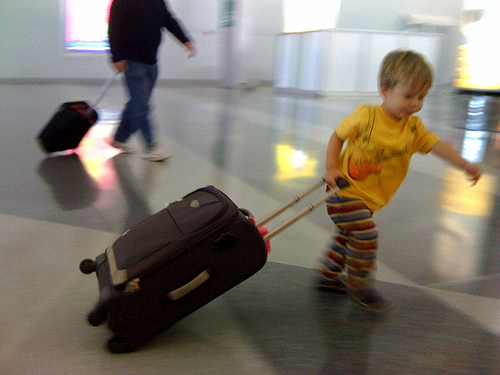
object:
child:
[309, 49, 484, 313]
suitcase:
[78, 174, 350, 355]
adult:
[102, 0, 198, 160]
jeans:
[115, 62, 160, 147]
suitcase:
[35, 65, 127, 155]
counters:
[267, 26, 442, 102]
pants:
[317, 184, 379, 294]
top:
[328, 104, 441, 211]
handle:
[319, 172, 351, 192]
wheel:
[108, 336, 129, 353]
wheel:
[86, 310, 106, 328]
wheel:
[79, 258, 96, 274]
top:
[107, 1, 195, 66]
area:
[274, 142, 318, 183]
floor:
[1, 80, 500, 374]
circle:
[289, 151, 307, 169]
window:
[63, 0, 111, 52]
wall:
[1, 0, 219, 80]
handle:
[116, 60, 129, 73]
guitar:
[347, 147, 410, 181]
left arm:
[418, 127, 482, 189]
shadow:
[306, 276, 382, 375]